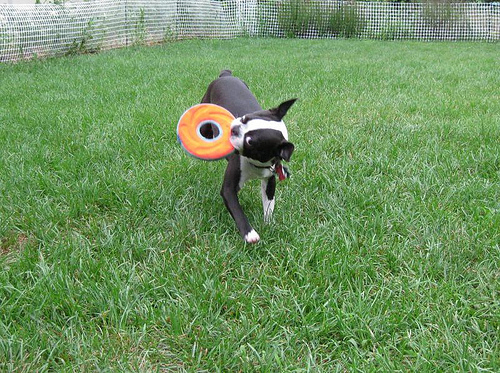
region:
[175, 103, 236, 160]
frisbee is round and orange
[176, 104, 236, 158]
round frisbee in dog's mouth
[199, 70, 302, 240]
Black and white dog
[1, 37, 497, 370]
dog is on green grass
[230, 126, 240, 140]
Dog has black nose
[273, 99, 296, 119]
Dog has black ear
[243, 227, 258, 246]
white paw on dog's black leg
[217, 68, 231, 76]
dog has black tail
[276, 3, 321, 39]
bush is against fence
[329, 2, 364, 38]
bush is behind green grass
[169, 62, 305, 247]
Frisbee in a dog's mouth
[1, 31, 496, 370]
Dog standing on the grass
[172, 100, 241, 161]
Frisbee has a hole in it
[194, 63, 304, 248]
The dog is black and white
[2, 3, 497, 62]
A white fence around the grass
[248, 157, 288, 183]
Collar around dog's neck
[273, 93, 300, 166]
Two ears of a dog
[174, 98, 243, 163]
The frisbee is orange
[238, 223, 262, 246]
A dog's white paw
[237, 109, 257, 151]
A pair of dog eyes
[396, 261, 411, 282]
part of a lawn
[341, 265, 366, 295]
part of a field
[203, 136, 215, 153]
part of a flier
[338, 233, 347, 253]
edge of a lawn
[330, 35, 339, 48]
part of a fence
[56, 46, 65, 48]
edge of a fence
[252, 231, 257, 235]
tip of a leg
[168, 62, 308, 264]
Black and white Boston Terrier.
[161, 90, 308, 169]
Don carrying a flying ring.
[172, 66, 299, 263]
Dice is walking through the grass.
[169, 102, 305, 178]
Dice the dog is wearing a collar.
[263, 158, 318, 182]
There is a tag on the dog's collar.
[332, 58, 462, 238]
Bright green grass in the yard.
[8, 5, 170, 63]
White fence to keep the dog safe.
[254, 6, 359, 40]
Long grass growing through the fence.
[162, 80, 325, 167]
The dog has his head tilted sideways.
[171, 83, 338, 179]
Dice enjoys playing with the flying ring.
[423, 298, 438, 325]
part of a lawn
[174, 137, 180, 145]
part of a flier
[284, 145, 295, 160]
ear of a dog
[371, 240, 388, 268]
part of a field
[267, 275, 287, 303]
edge of a plain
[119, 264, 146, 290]
part of a garden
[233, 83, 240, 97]
back of a door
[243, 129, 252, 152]
eye of a dog